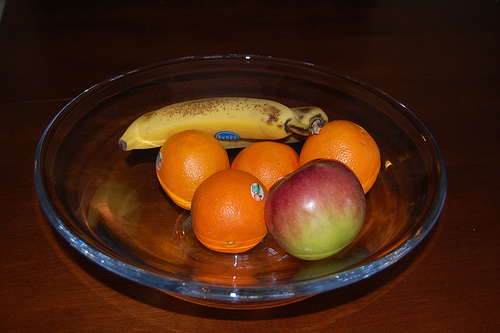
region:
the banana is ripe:
[147, 89, 290, 141]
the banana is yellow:
[132, 102, 313, 142]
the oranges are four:
[148, 128, 393, 243]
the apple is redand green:
[248, 171, 370, 261]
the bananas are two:
[155, 69, 331, 136]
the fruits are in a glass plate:
[71, 59, 474, 311]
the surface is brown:
[438, 254, 490, 330]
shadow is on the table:
[242, 303, 303, 320]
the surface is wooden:
[402, 51, 464, 96]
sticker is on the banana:
[212, 129, 243, 149]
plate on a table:
[48, 19, 454, 305]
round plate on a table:
[32, 49, 464, 326]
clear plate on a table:
[22, 41, 474, 298]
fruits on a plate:
[96, 90, 403, 254]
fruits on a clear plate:
[91, 75, 409, 259]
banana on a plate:
[100, 78, 337, 146]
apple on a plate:
[249, 153, 378, 253]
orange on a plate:
[141, 118, 240, 211]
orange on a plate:
[182, 165, 278, 255]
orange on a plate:
[303, 116, 385, 194]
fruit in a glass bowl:
[28, 46, 458, 316]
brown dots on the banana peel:
[151, 93, 281, 125]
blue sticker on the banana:
[213, 127, 243, 144]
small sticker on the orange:
[248, 183, 261, 200]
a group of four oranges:
[146, 120, 392, 259]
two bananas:
[119, 85, 336, 162]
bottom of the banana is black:
[112, 135, 129, 155]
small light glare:
[229, 290, 236, 297]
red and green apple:
[261, 160, 365, 267]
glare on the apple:
[298, 193, 319, 213]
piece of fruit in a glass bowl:
[260, 150, 370, 266]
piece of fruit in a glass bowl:
[185, 165, 266, 263]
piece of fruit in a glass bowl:
[151, 129, 231, 215]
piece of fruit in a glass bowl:
[114, 96, 311, 167]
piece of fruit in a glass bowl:
[230, 135, 302, 187]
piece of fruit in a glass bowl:
[300, 120, 386, 199]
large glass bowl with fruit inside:
[18, 43, 452, 314]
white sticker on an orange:
[247, 179, 264, 204]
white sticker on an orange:
[154, 150, 165, 172]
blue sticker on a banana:
[210, 127, 244, 146]